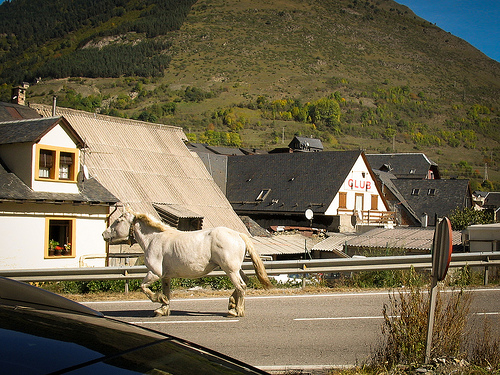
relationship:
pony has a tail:
[102, 200, 273, 320] [240, 231, 273, 292]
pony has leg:
[102, 200, 273, 320] [141, 266, 172, 310]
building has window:
[0, 79, 122, 270] [47, 219, 73, 257]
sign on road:
[429, 217, 454, 287] [77, 286, 498, 369]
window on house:
[47, 219, 73, 257] [196, 154, 395, 228]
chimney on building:
[10, 81, 28, 105] [0, 79, 122, 270]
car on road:
[1, 275, 273, 375] [77, 286, 498, 369]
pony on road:
[102, 200, 273, 320] [77, 286, 498, 369]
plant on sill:
[56, 242, 65, 250] [47, 255, 75, 259]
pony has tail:
[102, 200, 273, 320] [240, 231, 273, 292]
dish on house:
[301, 207, 315, 219] [196, 154, 395, 228]